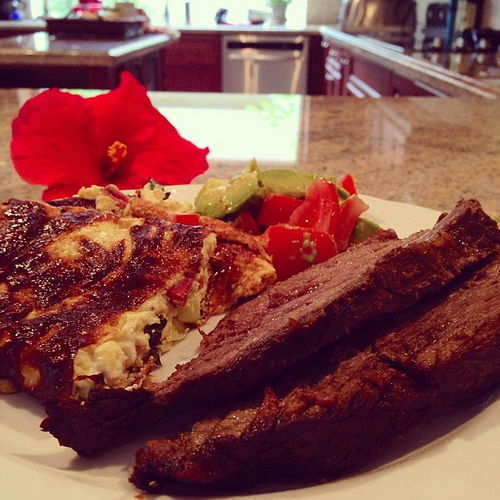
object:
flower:
[7, 67, 213, 207]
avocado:
[191, 156, 353, 220]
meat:
[128, 248, 500, 498]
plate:
[2, 181, 500, 498]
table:
[0, 83, 499, 499]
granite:
[0, 85, 499, 221]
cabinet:
[157, 30, 224, 93]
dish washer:
[219, 31, 312, 99]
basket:
[45, 16, 155, 46]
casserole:
[260, 222, 344, 285]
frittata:
[0, 175, 280, 412]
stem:
[101, 139, 128, 177]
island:
[0, 27, 184, 71]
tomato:
[232, 207, 263, 238]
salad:
[188, 158, 389, 289]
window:
[186, 0, 311, 38]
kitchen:
[0, 0, 499, 499]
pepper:
[255, 189, 304, 227]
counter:
[2, 84, 500, 216]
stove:
[413, 0, 457, 57]